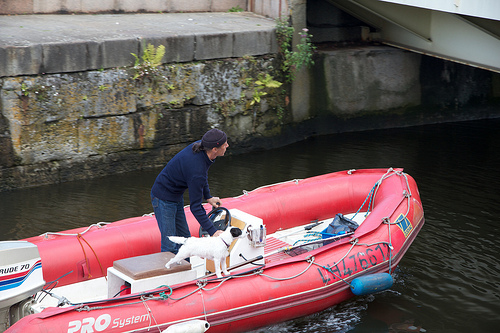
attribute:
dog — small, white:
[169, 228, 247, 278]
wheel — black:
[199, 203, 231, 239]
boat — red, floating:
[6, 165, 425, 332]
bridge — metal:
[349, 2, 499, 77]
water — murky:
[278, 130, 500, 332]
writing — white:
[63, 310, 152, 332]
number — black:
[319, 240, 392, 288]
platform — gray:
[4, 9, 281, 49]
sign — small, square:
[397, 212, 414, 239]